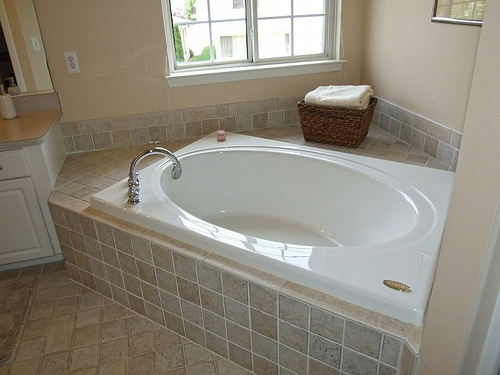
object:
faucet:
[127, 146, 183, 205]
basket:
[297, 94, 378, 148]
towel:
[305, 85, 374, 110]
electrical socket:
[64, 51, 81, 74]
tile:
[0, 94, 464, 374]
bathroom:
[0, 0, 500, 375]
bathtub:
[90, 130, 455, 329]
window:
[160, 0, 347, 89]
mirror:
[0, 0, 55, 99]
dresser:
[0, 108, 66, 272]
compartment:
[0, 143, 64, 273]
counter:
[0, 110, 63, 150]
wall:
[33, 1, 363, 123]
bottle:
[217, 130, 226, 141]